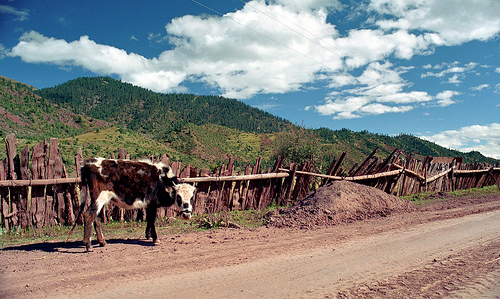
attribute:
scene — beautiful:
[2, 3, 497, 297]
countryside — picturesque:
[1, 0, 496, 295]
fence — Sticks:
[186, 161, 397, 200]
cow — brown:
[49, 138, 233, 293]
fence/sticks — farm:
[7, 140, 382, 213]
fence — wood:
[0, 135, 499, 231]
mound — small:
[262, 159, 416, 247]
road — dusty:
[0, 182, 494, 294]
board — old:
[176, 164, 368, 212]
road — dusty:
[1, 193, 497, 297]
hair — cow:
[32, 142, 44, 179]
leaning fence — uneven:
[282, 142, 415, 206]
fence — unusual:
[192, 157, 498, 201]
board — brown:
[2, 132, 21, 186]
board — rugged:
[45, 132, 57, 183]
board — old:
[72, 144, 85, 178]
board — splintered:
[324, 148, 354, 188]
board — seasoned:
[218, 151, 240, 206]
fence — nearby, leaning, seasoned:
[0, 126, 496, 227]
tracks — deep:
[352, 241, 484, 297]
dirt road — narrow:
[13, 195, 498, 294]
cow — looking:
[169, 182, 203, 219]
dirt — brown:
[332, 216, 495, 273]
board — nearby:
[171, 151, 188, 183]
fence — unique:
[225, 95, 486, 235]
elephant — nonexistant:
[4, 131, 498, 226]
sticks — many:
[0, 132, 499, 230]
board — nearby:
[45, 133, 61, 223]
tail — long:
[63, 182, 88, 247]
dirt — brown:
[279, 185, 433, 262]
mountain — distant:
[5, 76, 288, 145]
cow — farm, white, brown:
[65, 153, 200, 250]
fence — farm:
[189, 178, 317, 229]